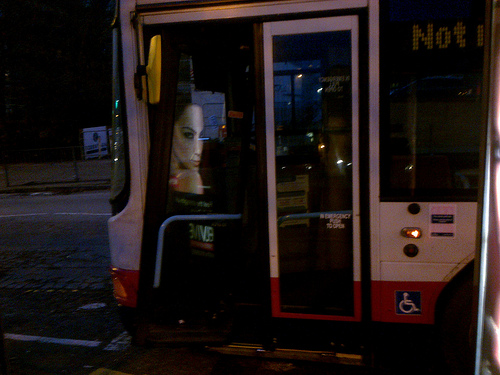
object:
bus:
[87, 2, 500, 375]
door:
[259, 14, 368, 325]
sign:
[392, 288, 424, 317]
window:
[164, 48, 237, 262]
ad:
[167, 100, 207, 193]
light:
[411, 229, 421, 238]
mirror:
[133, 33, 164, 105]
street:
[0, 185, 118, 375]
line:
[0, 329, 93, 348]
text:
[407, 17, 488, 52]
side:
[105, 4, 498, 375]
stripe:
[355, 7, 375, 338]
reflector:
[111, 268, 138, 308]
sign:
[402, 18, 493, 52]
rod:
[153, 213, 245, 290]